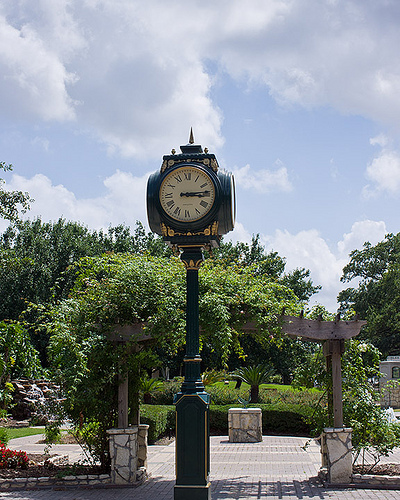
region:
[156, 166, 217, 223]
a clock on a metal pole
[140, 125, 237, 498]
a pole with a clock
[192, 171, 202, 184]
the number 1 in roman numerals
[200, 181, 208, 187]
the number 2 in roman numerals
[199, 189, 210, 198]
the number 3 in roman numerals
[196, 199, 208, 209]
the number 4 in roman numerals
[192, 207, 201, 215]
the number 5 in roman numerals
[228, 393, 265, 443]
a brick centerpiece with a statue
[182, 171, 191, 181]
the number 12 in roman numerals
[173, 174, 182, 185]
the number 11 in roman numerals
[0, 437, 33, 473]
Red flowers at the side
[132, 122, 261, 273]
A big stand clock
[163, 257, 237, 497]
Green pole at the center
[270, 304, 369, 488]
right isde of an arch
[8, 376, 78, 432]
Fountain at the left side background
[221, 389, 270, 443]
Statue at the center of the park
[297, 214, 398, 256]
Clouds at the far background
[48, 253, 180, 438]
Plants at the top of the arch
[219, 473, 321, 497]
Shadow of the arch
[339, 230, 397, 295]
A tree at the background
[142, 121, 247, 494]
green metal pole with gold trim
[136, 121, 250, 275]
green meatl clock with gold trim and white clockface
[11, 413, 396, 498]
brick tiled walkway in garden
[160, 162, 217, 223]
round white clockface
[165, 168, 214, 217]
black Roman numerals on clock reading 3:15 time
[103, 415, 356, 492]
stone posts on wooden arbor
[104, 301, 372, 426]
wooden arbor covered by green bushy growth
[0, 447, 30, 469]
small patch of red flowers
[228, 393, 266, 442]
square block of stone with green metal sculpture on top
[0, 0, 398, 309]
bright blue sky with white clouds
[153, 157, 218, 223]
round clock on a poll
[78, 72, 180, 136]
clear blue sky with clouds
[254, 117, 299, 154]
a clear blue skies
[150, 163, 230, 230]
an analog clock on a poll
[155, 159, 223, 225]
a round analog clock on a poll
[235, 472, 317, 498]
shadow on the floor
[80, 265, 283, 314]
bushes on the celing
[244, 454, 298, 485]
tile floor on the ground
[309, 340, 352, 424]
wooden pillar on a stone platform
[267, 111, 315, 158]
patch of blue sky with no clouds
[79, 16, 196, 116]
white fluffy cloud in sky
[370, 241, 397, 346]
trees growing in the background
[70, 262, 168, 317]
plants falling over wooden structure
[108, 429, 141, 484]
cobblestone half towers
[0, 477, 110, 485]
to the ground brick wall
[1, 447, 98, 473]
mulch and plants growing red flowers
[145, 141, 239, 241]
clocks on four sides of a rounded cube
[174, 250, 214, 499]
green and gold pole for holding clock structure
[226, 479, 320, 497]
shadow of wooden structure